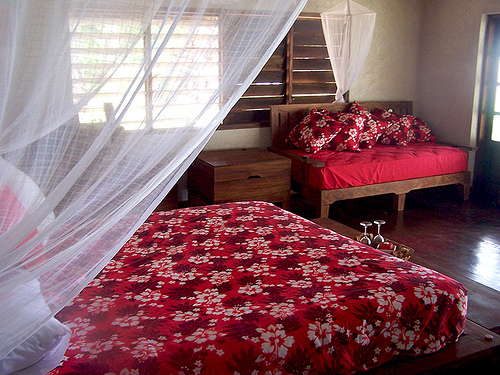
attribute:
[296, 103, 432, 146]
pillows — red, white, floral print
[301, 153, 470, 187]
couch — wooden, brown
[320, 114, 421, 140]
cushions — red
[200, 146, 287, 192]
table — brown, wood, brown wood, wooden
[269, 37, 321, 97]
blinds — wooden, brown, wood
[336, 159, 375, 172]
sheet — red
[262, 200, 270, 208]
sheet — white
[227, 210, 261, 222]
flowers — white, red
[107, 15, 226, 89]
drapes — white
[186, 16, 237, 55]
sheet — sheer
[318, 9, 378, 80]
shear cover — white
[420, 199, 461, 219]
flooring — hard wood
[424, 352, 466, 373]
bed frame — wood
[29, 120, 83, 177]
net — white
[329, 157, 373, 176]
bed sheet — red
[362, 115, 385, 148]
pillow — red, white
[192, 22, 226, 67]
curtain — white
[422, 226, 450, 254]
floor — dark wood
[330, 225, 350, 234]
tray — wood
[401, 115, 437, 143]
cushion — red